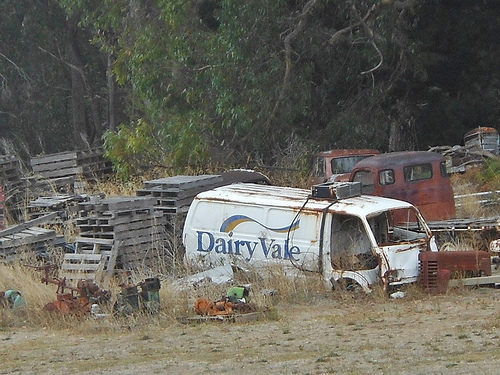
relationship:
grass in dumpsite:
[166, 313, 368, 371] [0, 124, 499, 327]